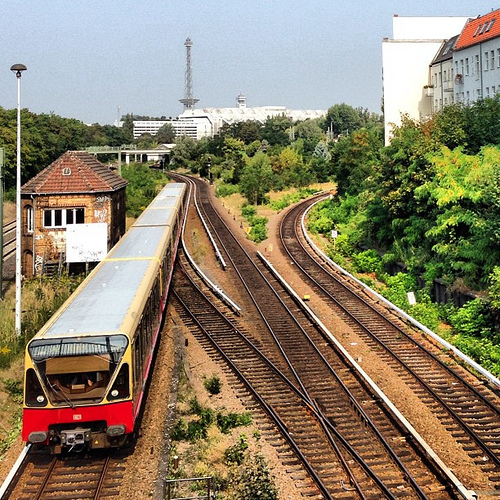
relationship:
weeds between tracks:
[162, 363, 264, 493] [194, 183, 497, 495]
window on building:
[73, 207, 88, 228] [20, 139, 131, 286]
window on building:
[44, 210, 51, 226] [7, 132, 134, 282]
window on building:
[76, 208, 85, 224] [7, 132, 134, 282]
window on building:
[46, 204, 65, 232] [7, 132, 134, 282]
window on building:
[56, 201, 78, 233] [7, 132, 134, 282]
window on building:
[76, 208, 85, 224] [1, 100, 191, 300]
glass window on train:
[136, 322, 153, 355] [20, 219, 189, 440]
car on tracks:
[21, 182, 188, 454] [195, 211, 464, 434]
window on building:
[42, 207, 65, 226] [10, 137, 132, 273]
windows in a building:
[430, 58, 474, 103] [429, 2, 484, 116]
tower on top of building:
[177, 37, 198, 112] [120, 104, 330, 145]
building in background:
[119, 104, 328, 139] [16, 22, 474, 150]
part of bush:
[435, 198, 445, 208] [400, 158, 495, 283]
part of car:
[144, 330, 213, 370] [21, 182, 188, 454]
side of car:
[114, 347, 138, 437] [21, 182, 188, 454]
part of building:
[101, 232, 117, 252] [20, 150, 130, 283]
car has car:
[21, 182, 188, 454] [134, 219, 181, 294]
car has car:
[21, 182, 188, 454] [134, 203, 184, 243]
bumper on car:
[28, 431, 47, 443] [21, 182, 188, 454]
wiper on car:
[42, 373, 74, 410] [21, 182, 188, 454]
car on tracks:
[21, 182, 188, 454] [12, 356, 136, 497]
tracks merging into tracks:
[184, 268, 339, 488] [254, 263, 417, 498]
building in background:
[114, 36, 328, 140] [84, 35, 484, 141]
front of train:
[20, 338, 135, 462] [1, 282, 131, 447]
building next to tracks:
[30, 149, 108, 254] [16, 467, 128, 494]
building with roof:
[451, 6, 498, 106] [454, 10, 498, 50]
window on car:
[30, 360, 137, 402] [21, 182, 188, 454]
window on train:
[147, 290, 164, 328] [126, 225, 170, 282]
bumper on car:
[103, 423, 130, 442] [21, 182, 188, 454]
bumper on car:
[27, 427, 51, 444] [21, 182, 188, 454]